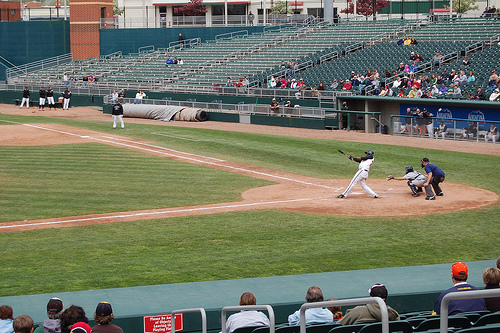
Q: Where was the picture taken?
A: It was taken at the stadium.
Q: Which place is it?
A: It is a stadium.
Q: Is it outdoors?
A: Yes, it is outdoors.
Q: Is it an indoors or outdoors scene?
A: It is outdoors.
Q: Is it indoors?
A: No, it is outdoors.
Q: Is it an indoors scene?
A: No, it is outdoors.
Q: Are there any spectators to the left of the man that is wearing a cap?
A: Yes, there is a spectator to the left of the man.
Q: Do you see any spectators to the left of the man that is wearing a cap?
A: Yes, there is a spectator to the left of the man.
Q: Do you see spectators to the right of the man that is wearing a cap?
A: No, the spectator is to the left of the man.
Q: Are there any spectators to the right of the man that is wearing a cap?
A: No, the spectator is to the left of the man.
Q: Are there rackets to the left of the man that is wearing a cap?
A: No, there is a spectator to the left of the man.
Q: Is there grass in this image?
A: Yes, there is grass.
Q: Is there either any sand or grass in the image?
A: Yes, there is grass.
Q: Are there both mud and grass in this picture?
A: No, there is grass but no mud.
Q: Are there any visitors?
A: No, there are no visitors.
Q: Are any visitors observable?
A: No, there are no visitors.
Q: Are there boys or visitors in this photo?
A: No, there are no visitors or boys.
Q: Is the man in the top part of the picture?
A: No, the man is in the bottom of the image.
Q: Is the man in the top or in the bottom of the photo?
A: The man is in the bottom of the image.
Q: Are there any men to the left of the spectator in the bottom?
A: Yes, there is a man to the left of the spectator.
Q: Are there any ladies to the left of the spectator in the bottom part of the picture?
A: No, there is a man to the left of the spectator.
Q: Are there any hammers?
A: No, there are no hammers.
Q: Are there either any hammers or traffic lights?
A: No, there are no hammers or traffic lights.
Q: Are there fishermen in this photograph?
A: No, there are no fishermen.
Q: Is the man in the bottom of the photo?
A: Yes, the man is in the bottom of the image.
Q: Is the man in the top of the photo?
A: No, the man is in the bottom of the image.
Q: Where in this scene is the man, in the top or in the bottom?
A: The man is in the bottom of the image.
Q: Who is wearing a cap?
A: The man is wearing a cap.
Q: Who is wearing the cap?
A: The man is wearing a cap.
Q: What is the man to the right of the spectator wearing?
A: The man is wearing a cap.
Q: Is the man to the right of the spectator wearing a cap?
A: Yes, the man is wearing a cap.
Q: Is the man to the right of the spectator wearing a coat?
A: No, the man is wearing a cap.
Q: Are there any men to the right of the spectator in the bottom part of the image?
A: Yes, there is a man to the right of the spectator.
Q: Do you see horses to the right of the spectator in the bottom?
A: No, there is a man to the right of the spectator.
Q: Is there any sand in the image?
A: Yes, there is sand.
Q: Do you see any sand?
A: Yes, there is sand.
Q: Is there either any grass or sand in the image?
A: Yes, there is sand.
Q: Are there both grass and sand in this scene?
A: Yes, there are both sand and grass.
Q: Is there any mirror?
A: No, there are no mirrors.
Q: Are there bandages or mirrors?
A: No, there are no mirrors or bandages.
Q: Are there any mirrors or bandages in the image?
A: No, there are no mirrors or bandages.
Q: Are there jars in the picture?
A: No, there are no jars.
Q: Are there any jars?
A: No, there are no jars.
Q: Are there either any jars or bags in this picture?
A: No, there are no jars or bags.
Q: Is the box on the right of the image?
A: Yes, the box is on the right of the image.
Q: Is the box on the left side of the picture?
A: No, the box is on the right of the image.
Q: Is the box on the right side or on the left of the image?
A: The box is on the right of the image.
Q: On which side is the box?
A: The box is on the right of the image.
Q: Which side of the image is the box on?
A: The box is on the right of the image.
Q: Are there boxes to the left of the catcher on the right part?
A: Yes, there is a box to the left of the catcher.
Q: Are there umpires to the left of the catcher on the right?
A: No, there is a box to the left of the catcher.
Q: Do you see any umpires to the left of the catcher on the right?
A: No, there is a box to the left of the catcher.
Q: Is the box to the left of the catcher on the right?
A: Yes, the box is to the left of the catcher.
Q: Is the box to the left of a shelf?
A: No, the box is to the left of the catcher.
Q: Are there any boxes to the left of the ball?
A: Yes, there is a box to the left of the ball.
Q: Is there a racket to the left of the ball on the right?
A: No, there is a box to the left of the ball.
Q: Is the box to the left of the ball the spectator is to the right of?
A: Yes, the box is to the left of the ball.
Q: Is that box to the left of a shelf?
A: No, the box is to the left of the ball.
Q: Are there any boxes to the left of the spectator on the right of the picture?
A: Yes, there is a box to the left of the spectator.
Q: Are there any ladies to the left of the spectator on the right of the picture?
A: No, there is a box to the left of the spectator.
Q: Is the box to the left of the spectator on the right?
A: Yes, the box is to the left of the spectator.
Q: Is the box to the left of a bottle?
A: No, the box is to the left of the spectator.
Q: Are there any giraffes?
A: No, there are no giraffes.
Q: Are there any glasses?
A: No, there are no glasses.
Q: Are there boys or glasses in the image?
A: No, there are no glasses or boys.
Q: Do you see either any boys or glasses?
A: No, there are no glasses or boys.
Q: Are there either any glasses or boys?
A: No, there are no glasses or boys.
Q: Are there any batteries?
A: No, there are no batteries.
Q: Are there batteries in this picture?
A: No, there are no batteries.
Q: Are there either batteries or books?
A: No, there are no batteries or books.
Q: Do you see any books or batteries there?
A: No, there are no batteries or books.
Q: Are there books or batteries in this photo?
A: No, there are no batteries or books.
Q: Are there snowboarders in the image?
A: No, there are no snowboarders.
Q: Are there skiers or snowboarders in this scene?
A: No, there are no snowboarders or skiers.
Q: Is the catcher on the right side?
A: Yes, the catcher is on the right of the image.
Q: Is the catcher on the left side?
A: No, the catcher is on the right of the image.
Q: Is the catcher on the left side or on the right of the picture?
A: The catcher is on the right of the image.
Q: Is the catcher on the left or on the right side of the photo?
A: The catcher is on the right of the image.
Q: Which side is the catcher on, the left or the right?
A: The catcher is on the right of the image.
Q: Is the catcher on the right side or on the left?
A: The catcher is on the right of the image.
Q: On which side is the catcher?
A: The catcher is on the right of the image.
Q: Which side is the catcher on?
A: The catcher is on the right of the image.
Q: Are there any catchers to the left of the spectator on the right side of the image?
A: Yes, there is a catcher to the left of the spectator.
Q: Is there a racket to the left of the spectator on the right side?
A: No, there is a catcher to the left of the spectator.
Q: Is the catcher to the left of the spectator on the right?
A: Yes, the catcher is to the left of the spectator.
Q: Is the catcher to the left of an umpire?
A: No, the catcher is to the left of the spectator.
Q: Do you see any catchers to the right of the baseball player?
A: Yes, there is a catcher to the right of the player.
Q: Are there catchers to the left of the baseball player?
A: No, the catcher is to the right of the player.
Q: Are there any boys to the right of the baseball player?
A: No, there is a catcher to the right of the player.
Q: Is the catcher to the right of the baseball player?
A: Yes, the catcher is to the right of the player.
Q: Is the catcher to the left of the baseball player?
A: No, the catcher is to the right of the player.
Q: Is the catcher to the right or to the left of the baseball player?
A: The catcher is to the right of the player.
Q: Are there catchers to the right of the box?
A: Yes, there is a catcher to the right of the box.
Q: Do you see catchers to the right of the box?
A: Yes, there is a catcher to the right of the box.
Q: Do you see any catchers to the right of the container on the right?
A: Yes, there is a catcher to the right of the box.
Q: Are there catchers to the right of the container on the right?
A: Yes, there is a catcher to the right of the box.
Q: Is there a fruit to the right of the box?
A: No, there is a catcher to the right of the box.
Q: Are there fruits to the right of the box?
A: No, there is a catcher to the right of the box.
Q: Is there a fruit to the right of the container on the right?
A: No, there is a catcher to the right of the box.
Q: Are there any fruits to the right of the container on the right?
A: No, there is a catcher to the right of the box.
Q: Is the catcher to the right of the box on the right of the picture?
A: Yes, the catcher is to the right of the box.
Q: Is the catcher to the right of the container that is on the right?
A: Yes, the catcher is to the right of the box.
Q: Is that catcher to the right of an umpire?
A: No, the catcher is to the right of the box.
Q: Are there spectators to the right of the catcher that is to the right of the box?
A: Yes, there is a spectator to the right of the catcher.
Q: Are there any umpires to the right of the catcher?
A: No, there is a spectator to the right of the catcher.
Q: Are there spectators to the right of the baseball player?
A: Yes, there is a spectator to the right of the player.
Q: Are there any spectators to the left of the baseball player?
A: No, the spectator is to the right of the player.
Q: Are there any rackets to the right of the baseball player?
A: No, there is a spectator to the right of the player.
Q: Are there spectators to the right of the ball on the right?
A: Yes, there is a spectator to the right of the ball.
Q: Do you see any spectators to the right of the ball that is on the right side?
A: Yes, there is a spectator to the right of the ball.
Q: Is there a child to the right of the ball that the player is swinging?
A: No, there is a spectator to the right of the ball.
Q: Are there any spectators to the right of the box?
A: Yes, there is a spectator to the right of the box.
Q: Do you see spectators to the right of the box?
A: Yes, there is a spectator to the right of the box.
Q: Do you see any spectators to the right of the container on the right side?
A: Yes, there is a spectator to the right of the box.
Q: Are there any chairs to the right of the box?
A: No, there is a spectator to the right of the box.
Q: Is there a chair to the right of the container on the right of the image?
A: No, there is a spectator to the right of the box.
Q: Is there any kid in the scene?
A: No, there are no children.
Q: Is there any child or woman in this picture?
A: No, there are no children or women.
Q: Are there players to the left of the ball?
A: Yes, there is a player to the left of the ball.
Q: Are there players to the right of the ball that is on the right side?
A: No, the player is to the left of the ball.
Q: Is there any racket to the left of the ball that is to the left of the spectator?
A: No, there is a player to the left of the ball.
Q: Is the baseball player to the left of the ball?
A: Yes, the player is to the left of the ball.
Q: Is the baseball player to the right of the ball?
A: No, the player is to the left of the ball.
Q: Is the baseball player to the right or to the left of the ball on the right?
A: The player is to the left of the ball.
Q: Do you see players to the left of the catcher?
A: Yes, there is a player to the left of the catcher.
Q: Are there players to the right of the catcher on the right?
A: No, the player is to the left of the catcher.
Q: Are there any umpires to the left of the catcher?
A: No, there is a player to the left of the catcher.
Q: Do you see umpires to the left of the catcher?
A: No, there is a player to the left of the catcher.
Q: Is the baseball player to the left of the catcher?
A: Yes, the player is to the left of the catcher.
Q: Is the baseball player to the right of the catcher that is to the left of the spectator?
A: No, the player is to the left of the catcher.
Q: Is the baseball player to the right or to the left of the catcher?
A: The player is to the left of the catcher.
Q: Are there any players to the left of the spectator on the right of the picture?
A: Yes, there is a player to the left of the spectator.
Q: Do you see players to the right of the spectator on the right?
A: No, the player is to the left of the spectator.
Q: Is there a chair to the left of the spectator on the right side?
A: No, there is a player to the left of the spectator.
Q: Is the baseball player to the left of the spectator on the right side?
A: Yes, the player is to the left of the spectator.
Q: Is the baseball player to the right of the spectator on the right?
A: No, the player is to the left of the spectator.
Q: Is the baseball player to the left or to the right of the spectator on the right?
A: The player is to the left of the spectator.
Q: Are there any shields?
A: No, there are no shields.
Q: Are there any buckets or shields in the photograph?
A: No, there are no shields or buckets.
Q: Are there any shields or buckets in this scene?
A: No, there are no shields or buckets.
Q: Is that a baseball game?
A: Yes, that is a baseball game.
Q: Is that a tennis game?
A: No, that is a baseball game.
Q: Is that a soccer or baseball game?
A: That is a baseball game.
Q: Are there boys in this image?
A: No, there are no boys.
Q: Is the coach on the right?
A: Yes, the coach is on the right of the image.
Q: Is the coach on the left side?
A: No, the coach is on the right of the image.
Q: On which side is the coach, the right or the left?
A: The coach is on the right of the image.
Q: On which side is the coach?
A: The coach is on the right of the image.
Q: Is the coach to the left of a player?
A: Yes, the coach is to the left of a player.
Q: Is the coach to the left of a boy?
A: No, the coach is to the left of a player.